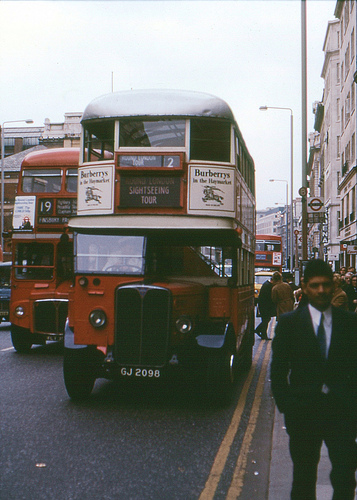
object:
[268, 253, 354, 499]
man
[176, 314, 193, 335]
headlight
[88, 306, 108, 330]
headlight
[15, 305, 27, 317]
headlight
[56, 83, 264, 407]
bus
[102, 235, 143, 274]
driver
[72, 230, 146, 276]
windshield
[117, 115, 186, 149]
window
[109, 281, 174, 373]
grill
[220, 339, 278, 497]
line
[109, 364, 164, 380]
tag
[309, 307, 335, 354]
shirt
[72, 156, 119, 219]
advertisement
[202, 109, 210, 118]
dent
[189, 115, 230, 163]
window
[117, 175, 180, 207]
sign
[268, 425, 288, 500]
pavement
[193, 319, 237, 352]
fender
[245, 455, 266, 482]
litter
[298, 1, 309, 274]
pole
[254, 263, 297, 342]
people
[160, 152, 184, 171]
numeration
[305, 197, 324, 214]
sign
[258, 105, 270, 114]
lamp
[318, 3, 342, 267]
building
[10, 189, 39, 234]
advertising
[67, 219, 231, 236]
levels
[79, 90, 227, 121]
roof